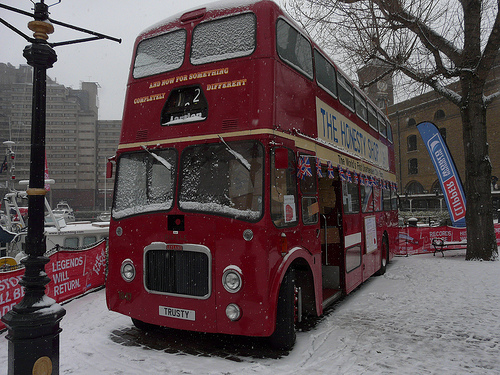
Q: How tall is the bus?
A: It's a double decker.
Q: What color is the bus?
A: Red.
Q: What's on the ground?
A: Snow.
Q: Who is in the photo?
A: No one.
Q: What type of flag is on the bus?
A: British.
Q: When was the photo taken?
A: During the day.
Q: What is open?
A: The door.